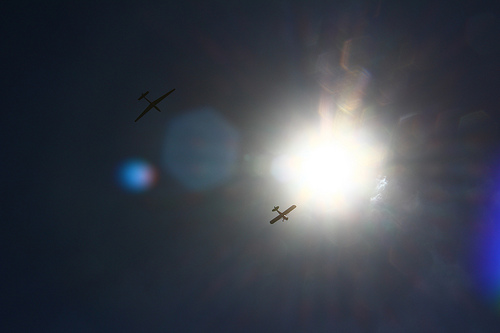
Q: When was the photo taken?
A: Night time.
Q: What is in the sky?
A: A plane.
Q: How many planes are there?
A: One.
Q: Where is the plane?
A: The sky.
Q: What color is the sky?
A: Black.